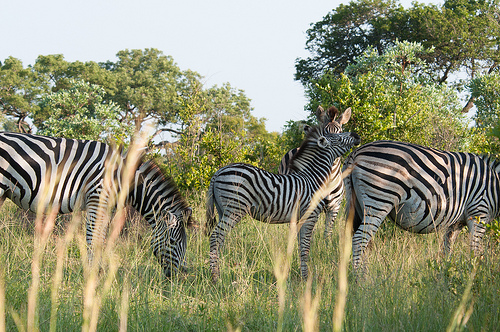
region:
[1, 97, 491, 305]
a small group of zebra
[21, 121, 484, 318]
some tall grass is in front of the zebra at this angel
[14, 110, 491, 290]
the zebra are covered in black and white stripes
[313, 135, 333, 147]
the baby zebras ear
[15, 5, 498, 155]
trees are behind the zebra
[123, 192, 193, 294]
the zebra is grazing in the field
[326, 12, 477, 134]
the trees are covered with green leaves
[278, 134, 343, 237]
a zebra stands behind the baby zebra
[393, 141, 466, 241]
the zebras body is visible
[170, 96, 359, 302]
zebra's fur is stripes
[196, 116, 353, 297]
zebra's fur is stripes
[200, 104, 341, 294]
zebra's fur is stripes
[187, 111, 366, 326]
zebra's fur is stripes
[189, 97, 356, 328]
zebra's fur is stripes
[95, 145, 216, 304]
zebra is eating grass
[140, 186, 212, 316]
zebra is eating grass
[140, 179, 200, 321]
zebra is eating grass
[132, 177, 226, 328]
zebra is eating grass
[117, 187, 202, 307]
zebra is eating grass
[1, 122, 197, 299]
This is a zebra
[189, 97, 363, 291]
This is a zebra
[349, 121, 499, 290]
This is a zebra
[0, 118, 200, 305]
This is a zebra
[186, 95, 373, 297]
This is a zebra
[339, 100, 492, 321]
This is a zebra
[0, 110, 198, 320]
This is a zebra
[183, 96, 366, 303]
This is a zebra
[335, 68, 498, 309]
This is a zebra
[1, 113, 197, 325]
This is a zebra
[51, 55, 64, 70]
green leaves on tree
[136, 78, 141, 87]
green leaves on tree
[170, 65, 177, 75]
green leaves on tree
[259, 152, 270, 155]
green leaves on tree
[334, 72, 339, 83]
green leaves on tree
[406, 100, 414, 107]
green leaves on tree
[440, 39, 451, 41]
green leaves on tree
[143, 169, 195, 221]
Black and white stripes on an animal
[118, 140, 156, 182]
Black and white stripes on an animal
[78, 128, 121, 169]
Black and white stripes on an animal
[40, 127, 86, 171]
Black and white stripes on an animal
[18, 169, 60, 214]
Black and white stripes on an animal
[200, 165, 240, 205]
Black and white stripes on an animal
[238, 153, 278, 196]
Black and white stripes on an animal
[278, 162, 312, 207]
Black and white stripes on an animal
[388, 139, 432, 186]
Black and white stripes on an animal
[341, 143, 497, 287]
A zebra is standing in the grass.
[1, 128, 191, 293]
A large zebra is grazing.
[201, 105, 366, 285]
A baby zebra is standing between two large zebras.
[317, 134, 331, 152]
The baby zebra has a small ear.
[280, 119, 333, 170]
The baby zebra has a mane.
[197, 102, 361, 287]
The baby zebra is striped.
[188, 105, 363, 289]
The baby zebra is black and white.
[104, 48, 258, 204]
There is a tree behind the zebras.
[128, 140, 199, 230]
The zebra that is grazing has a mane.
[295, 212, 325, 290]
The right front leg of the baby zebra.